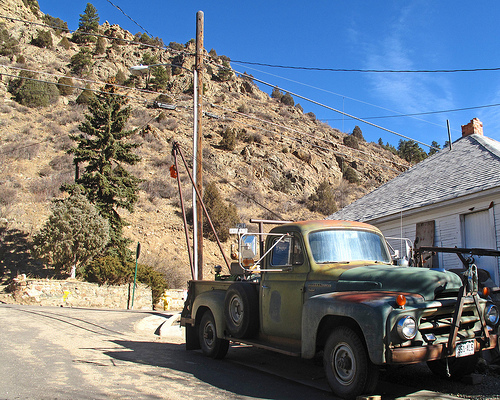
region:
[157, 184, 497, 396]
truck parked on the side of the road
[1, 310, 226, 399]
light brown dirt on the road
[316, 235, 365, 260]
light shining on the windshield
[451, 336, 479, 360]
license plate on the front of the truck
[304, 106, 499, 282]
white building with a gray roof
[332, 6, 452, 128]
thin white cloud in the sky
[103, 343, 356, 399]
shadow from the truck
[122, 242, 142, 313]
green pole sticking out of the ground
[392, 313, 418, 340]
circular light on the front of the truck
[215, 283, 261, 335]
spare tire on the side of the truck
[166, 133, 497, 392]
an old truck is parked by the house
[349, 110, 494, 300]
an older white house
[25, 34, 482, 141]
power lines run across the area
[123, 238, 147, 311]
a stop sign in the background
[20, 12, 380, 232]
a rocky hill side is behind the truck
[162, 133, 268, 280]
the truck is equipped with towing equipment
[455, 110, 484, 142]
the house has a chimney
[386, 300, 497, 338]
the trucks headlights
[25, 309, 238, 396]
dirt is on the road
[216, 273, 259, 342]
a spare tire is attached to the side of the truck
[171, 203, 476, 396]
truck on the ground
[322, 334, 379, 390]
front tire of truck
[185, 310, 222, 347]
rear tire of truck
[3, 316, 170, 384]
road where truck sits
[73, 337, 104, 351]
dirt patch on the road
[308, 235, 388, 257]
window to front of vehicle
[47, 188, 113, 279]
small tree on land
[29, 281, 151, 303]
stone wall near ground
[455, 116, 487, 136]
chimney on the roof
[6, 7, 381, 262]
elevated terrain in back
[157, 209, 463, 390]
old truck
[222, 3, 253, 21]
white clouds in blue sky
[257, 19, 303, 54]
white clouds in blue sky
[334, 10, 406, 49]
white clouds in blue sky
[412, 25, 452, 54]
white clouds in blue sky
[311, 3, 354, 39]
white clouds in blue sky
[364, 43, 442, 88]
white clouds in blue sky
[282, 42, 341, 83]
white clouds in blue sky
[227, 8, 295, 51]
white clouds in blue sky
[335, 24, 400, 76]
white clouds in blue sky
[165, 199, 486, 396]
large green truck parked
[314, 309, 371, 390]
black tires in a truck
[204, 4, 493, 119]
clear blue sky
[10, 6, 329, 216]
trees on a mountain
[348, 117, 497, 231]
a white house beside the truck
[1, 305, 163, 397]
a road with dirt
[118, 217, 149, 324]
a green street sign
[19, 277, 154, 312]
cobblestone wall beside road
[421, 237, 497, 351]
front of truck used for towing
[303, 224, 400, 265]
dirty windshield on truck